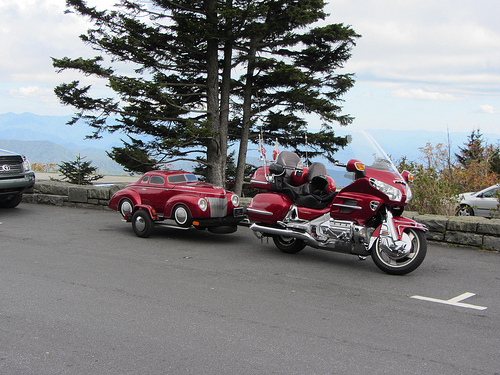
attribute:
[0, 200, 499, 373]
paved street — black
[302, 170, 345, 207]
helmet — red 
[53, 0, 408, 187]
tree — big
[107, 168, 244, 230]
red car — tiny 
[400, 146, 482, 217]
trees — green , orange 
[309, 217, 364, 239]
engine — silver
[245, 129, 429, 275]
motorcycle — parked, red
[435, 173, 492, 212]
car — parked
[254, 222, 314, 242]
exhaust — silver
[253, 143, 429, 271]
motorcycle — red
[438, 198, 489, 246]
fence — stone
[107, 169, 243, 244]
car — red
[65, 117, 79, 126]
leaf — green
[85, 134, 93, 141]
leaf — green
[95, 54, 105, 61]
leaf — green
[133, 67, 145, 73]
leaf — green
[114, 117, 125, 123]
leaf — green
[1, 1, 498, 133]
clouds — white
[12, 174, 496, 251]
wall — stone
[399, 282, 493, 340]
lines — white